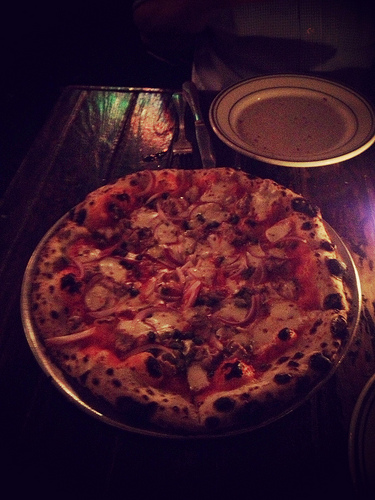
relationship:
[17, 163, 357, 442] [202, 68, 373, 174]
pizza on plate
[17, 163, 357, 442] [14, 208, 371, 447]
pizza on platter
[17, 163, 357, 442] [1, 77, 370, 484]
pizza on table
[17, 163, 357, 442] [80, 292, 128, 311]
pizza with cheese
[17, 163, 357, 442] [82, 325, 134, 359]
pizza with tomato sauce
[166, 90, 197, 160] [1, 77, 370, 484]
fork on table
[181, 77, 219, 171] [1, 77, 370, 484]
knife on table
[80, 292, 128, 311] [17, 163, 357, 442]
cheese on pizza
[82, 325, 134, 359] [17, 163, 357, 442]
tomato sauce on pizza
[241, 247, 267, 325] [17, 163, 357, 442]
onions on pizza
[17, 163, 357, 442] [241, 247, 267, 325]
pizza with onions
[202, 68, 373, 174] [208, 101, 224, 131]
plate with lines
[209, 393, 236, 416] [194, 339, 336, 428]
circle on crust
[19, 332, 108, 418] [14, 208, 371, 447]
edge of platter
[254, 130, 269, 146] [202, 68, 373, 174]
crumb on plate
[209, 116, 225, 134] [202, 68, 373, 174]
edge of plate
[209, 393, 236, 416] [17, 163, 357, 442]
circle on pizza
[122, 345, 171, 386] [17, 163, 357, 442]
bubble on pizza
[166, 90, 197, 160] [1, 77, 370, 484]
fork laying on table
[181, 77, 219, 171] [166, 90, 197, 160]
knife next to fork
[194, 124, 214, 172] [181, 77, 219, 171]
blade of knife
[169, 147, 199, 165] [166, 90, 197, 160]
tines of fork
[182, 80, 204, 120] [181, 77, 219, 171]
handle of knife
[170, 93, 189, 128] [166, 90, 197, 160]
handle of fork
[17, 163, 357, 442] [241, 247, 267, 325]
pizza has onions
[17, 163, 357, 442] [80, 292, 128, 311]
pizza has cheese